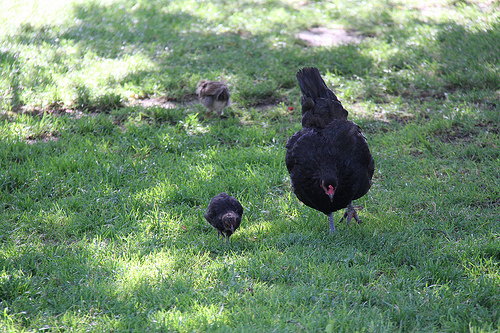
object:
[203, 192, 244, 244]
chicken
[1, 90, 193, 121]
dirt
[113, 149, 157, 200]
grass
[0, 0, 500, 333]
yard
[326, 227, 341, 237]
foot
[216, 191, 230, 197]
tail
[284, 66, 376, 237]
chicken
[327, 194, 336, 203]
beak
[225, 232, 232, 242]
leg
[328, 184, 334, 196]
comb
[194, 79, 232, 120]
bird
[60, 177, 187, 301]
ground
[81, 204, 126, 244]
spot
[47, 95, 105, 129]
shadow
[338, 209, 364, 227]
feet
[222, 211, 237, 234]
head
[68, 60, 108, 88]
light